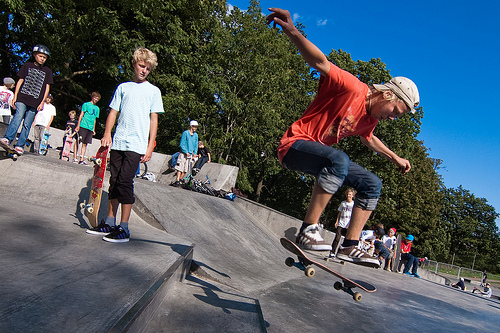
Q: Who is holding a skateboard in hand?
A: A boy.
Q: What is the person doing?
A: A trick on the skateboard.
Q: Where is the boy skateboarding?
A: On a ramp.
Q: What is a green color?
A: Trees.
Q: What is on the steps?
A: A shadow.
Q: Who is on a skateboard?
A: A man.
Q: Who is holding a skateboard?
A: A boy.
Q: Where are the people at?
A: Skate park.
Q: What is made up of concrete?
A: Skate part.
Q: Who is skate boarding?
A: A boy.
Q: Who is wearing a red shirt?
A: A skateboarder.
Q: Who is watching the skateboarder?
A: A boy.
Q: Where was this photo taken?
A: At a park.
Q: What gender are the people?
A: Male.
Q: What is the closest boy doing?
A: Skateboarding.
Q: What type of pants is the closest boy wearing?
A: Jeans.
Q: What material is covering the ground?
A: Concrete.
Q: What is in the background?
A: Trees.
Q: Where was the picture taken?
A: At a park.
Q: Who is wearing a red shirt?
A: Boy in the air.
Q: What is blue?
A: The sky.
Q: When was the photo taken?
A: Daytime.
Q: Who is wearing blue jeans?
A: Skateboarder in the air.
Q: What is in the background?
A: Trees.